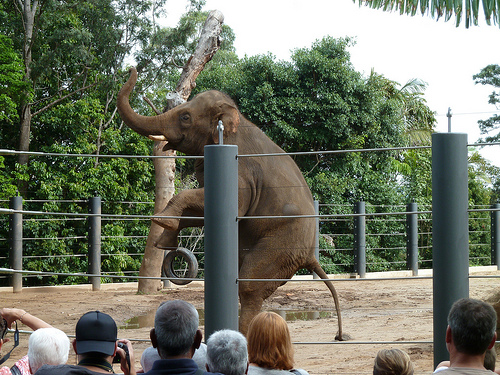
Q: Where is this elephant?
A: Fenced enclosure.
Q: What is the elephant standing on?
A: Dirt ground.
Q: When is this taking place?
A: Daytime.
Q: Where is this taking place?
A: At a game preserve.